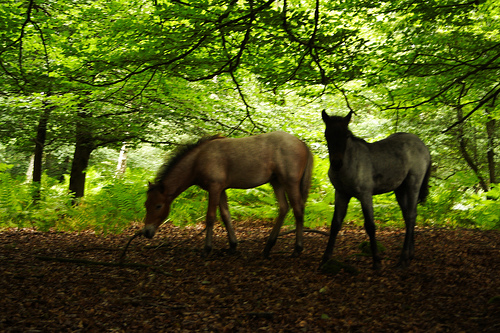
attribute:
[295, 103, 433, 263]
horse — cut, grey, black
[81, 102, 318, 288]
horse — brown, long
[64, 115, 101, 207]
trunk — tall, black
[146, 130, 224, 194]
mane — black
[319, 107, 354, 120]
ears — black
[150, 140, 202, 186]
mane — black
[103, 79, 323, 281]
horse. — brown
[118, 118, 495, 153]
horse — brown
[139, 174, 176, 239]
head — brown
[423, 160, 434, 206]
tail — black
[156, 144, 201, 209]
neck — brown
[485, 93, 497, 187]
trunk — tall, black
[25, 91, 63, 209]
trunk — tall, black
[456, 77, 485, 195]
trunk — tall, black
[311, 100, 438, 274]
horse — pale, white, grey, black